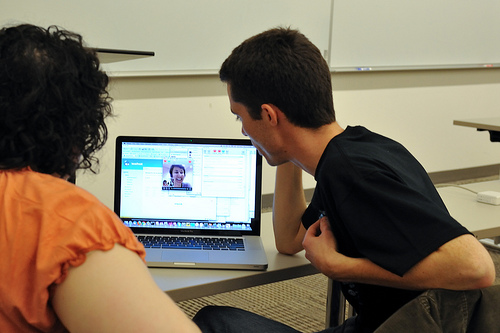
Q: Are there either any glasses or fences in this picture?
A: No, there are no fences or glasses.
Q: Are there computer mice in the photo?
A: Yes, there is a computer mouse.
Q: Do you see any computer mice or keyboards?
A: Yes, there is a computer mouse.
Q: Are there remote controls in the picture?
A: No, there are no remote controls.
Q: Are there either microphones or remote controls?
A: No, there are no remote controls or microphones.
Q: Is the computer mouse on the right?
A: Yes, the computer mouse is on the right of the image.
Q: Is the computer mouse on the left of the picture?
A: No, the computer mouse is on the right of the image.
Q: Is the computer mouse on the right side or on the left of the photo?
A: The computer mouse is on the right of the image.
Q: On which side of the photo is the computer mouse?
A: The computer mouse is on the right of the image.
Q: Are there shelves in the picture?
A: No, there are no shelves.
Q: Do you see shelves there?
A: No, there are no shelves.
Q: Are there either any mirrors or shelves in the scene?
A: No, there are no shelves or mirrors.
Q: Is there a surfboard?
A: No, there are no surfboards.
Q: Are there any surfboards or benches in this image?
A: No, there are no surfboards or benches.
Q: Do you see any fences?
A: No, there are no fences.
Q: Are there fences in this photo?
A: No, there are no fences.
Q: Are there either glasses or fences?
A: No, there are no fences or glasses.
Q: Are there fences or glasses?
A: No, there are no fences or glasses.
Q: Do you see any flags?
A: No, there are no flags.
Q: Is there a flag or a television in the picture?
A: No, there are no flags or televisions.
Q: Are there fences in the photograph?
A: No, there are no fences.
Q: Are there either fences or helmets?
A: No, there are no fences or helmets.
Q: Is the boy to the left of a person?
A: Yes, the boy is to the left of a person.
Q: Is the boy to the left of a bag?
A: No, the boy is to the left of a person.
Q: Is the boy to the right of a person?
A: No, the boy is to the left of a person.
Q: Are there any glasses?
A: No, there are no glasses.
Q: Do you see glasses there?
A: No, there are no glasses.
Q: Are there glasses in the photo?
A: No, there are no glasses.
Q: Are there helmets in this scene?
A: No, there are no helmets.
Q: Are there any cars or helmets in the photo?
A: No, there are no helmets or cars.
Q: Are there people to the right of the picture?
A: Yes, there is a person to the right of the picture.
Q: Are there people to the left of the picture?
A: No, the person is to the right of the picture.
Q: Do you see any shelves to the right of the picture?
A: No, there is a person to the right of the picture.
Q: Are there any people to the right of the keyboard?
A: Yes, there is a person to the right of the keyboard.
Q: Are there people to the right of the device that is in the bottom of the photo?
A: Yes, there is a person to the right of the keyboard.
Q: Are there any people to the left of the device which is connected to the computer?
A: No, the person is to the right of the keyboard.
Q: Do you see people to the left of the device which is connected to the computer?
A: No, the person is to the right of the keyboard.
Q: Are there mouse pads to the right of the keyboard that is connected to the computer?
A: No, there is a person to the right of the keyboard.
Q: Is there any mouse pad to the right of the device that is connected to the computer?
A: No, there is a person to the right of the keyboard.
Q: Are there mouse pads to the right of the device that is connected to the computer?
A: No, there is a person to the right of the keyboard.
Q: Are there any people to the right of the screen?
A: Yes, there is a person to the right of the screen.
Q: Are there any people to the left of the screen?
A: No, the person is to the right of the screen.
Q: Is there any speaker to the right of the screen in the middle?
A: No, there is a person to the right of the screen.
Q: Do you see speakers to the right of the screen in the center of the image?
A: No, there is a person to the right of the screen.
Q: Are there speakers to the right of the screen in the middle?
A: No, there is a person to the right of the screen.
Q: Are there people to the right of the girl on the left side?
A: Yes, there is a person to the right of the girl.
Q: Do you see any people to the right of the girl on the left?
A: Yes, there is a person to the right of the girl.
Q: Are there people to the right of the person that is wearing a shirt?
A: Yes, there is a person to the right of the girl.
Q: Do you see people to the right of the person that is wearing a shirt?
A: Yes, there is a person to the right of the girl.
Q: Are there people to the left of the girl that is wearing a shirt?
A: No, the person is to the right of the girl.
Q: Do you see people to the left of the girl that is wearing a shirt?
A: No, the person is to the right of the girl.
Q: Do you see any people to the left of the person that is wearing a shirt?
A: No, the person is to the right of the girl.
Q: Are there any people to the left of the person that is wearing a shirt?
A: No, the person is to the right of the girl.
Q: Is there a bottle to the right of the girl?
A: No, there is a person to the right of the girl.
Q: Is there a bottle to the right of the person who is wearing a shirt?
A: No, there is a person to the right of the girl.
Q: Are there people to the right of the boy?
A: Yes, there is a person to the right of the boy.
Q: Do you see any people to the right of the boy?
A: Yes, there is a person to the right of the boy.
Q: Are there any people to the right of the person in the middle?
A: Yes, there is a person to the right of the boy.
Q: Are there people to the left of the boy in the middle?
A: No, the person is to the right of the boy.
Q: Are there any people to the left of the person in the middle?
A: No, the person is to the right of the boy.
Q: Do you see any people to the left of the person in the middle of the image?
A: No, the person is to the right of the boy.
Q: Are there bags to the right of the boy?
A: No, there is a person to the right of the boy.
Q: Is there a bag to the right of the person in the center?
A: No, there is a person to the right of the boy.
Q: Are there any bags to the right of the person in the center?
A: No, there is a person to the right of the boy.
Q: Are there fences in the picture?
A: No, there are no fences.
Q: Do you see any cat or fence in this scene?
A: No, there are no fences or cats.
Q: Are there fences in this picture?
A: No, there are no fences.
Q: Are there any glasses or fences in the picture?
A: No, there are no fences or glasses.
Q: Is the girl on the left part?
A: Yes, the girl is on the left of the image.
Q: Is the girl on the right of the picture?
A: No, the girl is on the left of the image.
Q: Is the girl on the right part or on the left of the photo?
A: The girl is on the left of the image.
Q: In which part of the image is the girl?
A: The girl is on the left of the image.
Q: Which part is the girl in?
A: The girl is on the left of the image.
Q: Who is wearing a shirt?
A: The girl is wearing a shirt.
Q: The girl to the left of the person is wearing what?
A: The girl is wearing a shirt.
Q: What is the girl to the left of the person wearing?
A: The girl is wearing a shirt.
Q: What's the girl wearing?
A: The girl is wearing a shirt.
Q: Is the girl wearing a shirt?
A: Yes, the girl is wearing a shirt.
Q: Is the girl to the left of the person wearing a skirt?
A: No, the girl is wearing a shirt.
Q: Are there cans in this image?
A: No, there are no cans.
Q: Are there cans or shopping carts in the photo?
A: No, there are no cans or shopping carts.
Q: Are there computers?
A: Yes, there is a computer.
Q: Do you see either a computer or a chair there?
A: Yes, there is a computer.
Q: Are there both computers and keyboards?
A: Yes, there are both a computer and a keyboard.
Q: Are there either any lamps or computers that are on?
A: Yes, the computer is on.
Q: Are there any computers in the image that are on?
A: Yes, there is a computer that is on.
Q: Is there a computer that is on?
A: Yes, there is a computer that is on.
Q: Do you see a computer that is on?
A: Yes, there is a computer that is on.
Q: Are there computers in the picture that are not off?
A: Yes, there is a computer that is on.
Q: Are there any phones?
A: No, there are no phones.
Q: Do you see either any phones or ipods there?
A: No, there are no phones or ipods.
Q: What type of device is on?
A: The device is a computer.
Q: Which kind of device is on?
A: The device is a computer.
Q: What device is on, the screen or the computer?
A: The computer is on.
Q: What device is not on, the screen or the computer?
A: The screen is not on.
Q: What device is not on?
A: The device is a screen.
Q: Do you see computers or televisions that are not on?
A: No, there is a computer but it is on.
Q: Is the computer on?
A: Yes, the computer is on.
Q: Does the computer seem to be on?
A: Yes, the computer is on.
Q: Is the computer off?
A: No, the computer is on.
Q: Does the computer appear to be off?
A: No, the computer is on.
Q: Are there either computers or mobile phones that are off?
A: No, there is a computer but it is on.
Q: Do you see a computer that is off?
A: No, there is a computer but it is on.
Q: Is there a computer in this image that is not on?
A: No, there is a computer but it is on.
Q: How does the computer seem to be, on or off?
A: The computer is on.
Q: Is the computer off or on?
A: The computer is on.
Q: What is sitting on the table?
A: The computer is sitting on the table.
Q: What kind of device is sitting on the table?
A: The device is a computer.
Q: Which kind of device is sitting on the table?
A: The device is a computer.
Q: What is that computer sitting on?
A: The computer is sitting on the table.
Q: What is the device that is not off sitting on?
A: The computer is sitting on the table.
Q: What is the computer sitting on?
A: The computer is sitting on the table.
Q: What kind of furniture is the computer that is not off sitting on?
A: The computer is sitting on the table.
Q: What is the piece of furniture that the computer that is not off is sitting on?
A: The piece of furniture is a table.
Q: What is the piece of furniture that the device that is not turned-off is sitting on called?
A: The piece of furniture is a table.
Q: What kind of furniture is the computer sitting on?
A: The computer is sitting on the table.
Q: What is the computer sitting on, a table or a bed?
A: The computer is sitting on a table.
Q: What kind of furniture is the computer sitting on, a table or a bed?
A: The computer is sitting on a table.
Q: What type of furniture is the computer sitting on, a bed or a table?
A: The computer is sitting on a table.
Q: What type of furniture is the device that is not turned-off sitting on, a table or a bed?
A: The computer is sitting on a table.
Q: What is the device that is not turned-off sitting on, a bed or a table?
A: The computer is sitting on a table.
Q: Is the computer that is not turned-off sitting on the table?
A: Yes, the computer is sitting on the table.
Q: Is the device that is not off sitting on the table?
A: Yes, the computer is sitting on the table.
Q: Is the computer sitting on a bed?
A: No, the computer is sitting on the table.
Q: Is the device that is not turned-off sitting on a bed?
A: No, the computer is sitting on the table.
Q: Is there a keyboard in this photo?
A: Yes, there is a keyboard.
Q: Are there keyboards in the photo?
A: Yes, there is a keyboard.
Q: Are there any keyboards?
A: Yes, there is a keyboard.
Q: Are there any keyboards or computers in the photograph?
A: Yes, there is a keyboard.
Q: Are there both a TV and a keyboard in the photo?
A: No, there is a keyboard but no televisions.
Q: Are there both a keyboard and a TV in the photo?
A: No, there is a keyboard but no televisions.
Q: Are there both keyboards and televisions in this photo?
A: No, there is a keyboard but no televisions.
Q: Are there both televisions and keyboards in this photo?
A: No, there is a keyboard but no televisions.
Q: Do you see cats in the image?
A: No, there are no cats.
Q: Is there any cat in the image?
A: No, there are no cats.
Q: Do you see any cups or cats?
A: No, there are no cats or cups.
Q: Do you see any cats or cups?
A: No, there are no cats or cups.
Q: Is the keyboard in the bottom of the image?
A: Yes, the keyboard is in the bottom of the image.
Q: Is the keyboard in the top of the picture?
A: No, the keyboard is in the bottom of the image.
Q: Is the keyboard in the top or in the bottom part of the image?
A: The keyboard is in the bottom of the image.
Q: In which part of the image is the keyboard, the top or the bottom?
A: The keyboard is in the bottom of the image.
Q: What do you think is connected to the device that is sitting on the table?
A: The keyboard is connected to the computer.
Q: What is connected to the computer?
A: The keyboard is connected to the computer.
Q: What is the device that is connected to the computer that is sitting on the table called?
A: The device is a keyboard.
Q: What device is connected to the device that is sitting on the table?
A: The device is a keyboard.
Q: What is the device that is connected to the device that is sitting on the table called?
A: The device is a keyboard.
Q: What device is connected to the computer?
A: The device is a keyboard.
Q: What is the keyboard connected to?
A: The keyboard is connected to the computer.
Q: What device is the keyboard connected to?
A: The keyboard is connected to the computer.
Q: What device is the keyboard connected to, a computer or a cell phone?
A: The keyboard is connected to a computer.